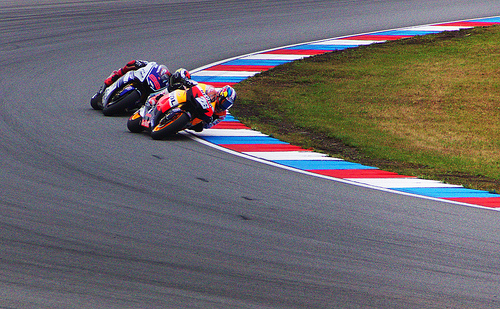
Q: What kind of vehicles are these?
A: Motorcycles.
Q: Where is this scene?
A: A race track.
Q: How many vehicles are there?
A: Two.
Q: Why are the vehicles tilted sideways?
A: Centripetal force.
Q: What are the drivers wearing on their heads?
A: Helmets.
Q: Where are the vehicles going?
A: In circles.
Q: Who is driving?
A: Racers.